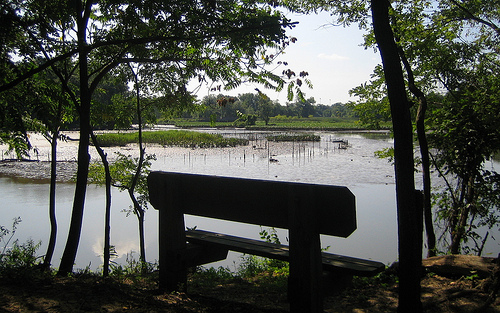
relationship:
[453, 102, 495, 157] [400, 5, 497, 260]
green leaves on tree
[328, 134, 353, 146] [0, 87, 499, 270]
log floating on pond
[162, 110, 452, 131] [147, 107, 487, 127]
grass near shoreline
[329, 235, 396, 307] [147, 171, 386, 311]
edge of bench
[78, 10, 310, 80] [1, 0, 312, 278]
leaves on tree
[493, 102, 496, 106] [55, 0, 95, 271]
green leaves on tree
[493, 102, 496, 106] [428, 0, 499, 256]
green leaves on tree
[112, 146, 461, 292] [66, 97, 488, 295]
bench next to water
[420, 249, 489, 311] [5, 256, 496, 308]
light on ground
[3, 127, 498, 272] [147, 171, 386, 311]
water near bench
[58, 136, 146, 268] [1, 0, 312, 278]
branches on tree